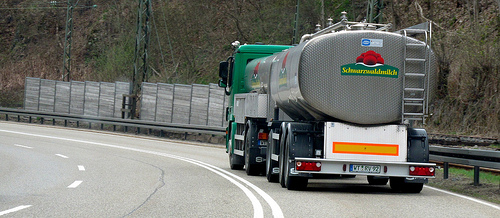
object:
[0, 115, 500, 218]
road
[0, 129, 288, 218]
curve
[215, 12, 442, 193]
truck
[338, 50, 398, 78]
tag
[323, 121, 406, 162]
tag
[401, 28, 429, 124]
ladder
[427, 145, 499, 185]
guard rail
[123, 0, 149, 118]
trees lining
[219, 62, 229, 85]
mirror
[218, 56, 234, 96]
black window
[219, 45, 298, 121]
cabin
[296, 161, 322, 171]
red lights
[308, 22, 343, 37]
pipes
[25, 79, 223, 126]
wood fence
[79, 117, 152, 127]
rails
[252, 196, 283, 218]
double lines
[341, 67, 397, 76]
yellow lettering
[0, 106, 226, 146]
railing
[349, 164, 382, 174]
license plate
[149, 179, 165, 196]
crack